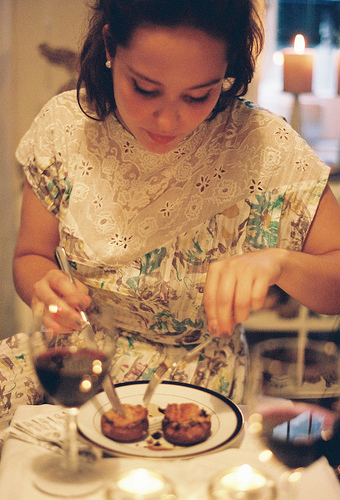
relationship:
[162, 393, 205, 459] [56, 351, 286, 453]
crab cake on plate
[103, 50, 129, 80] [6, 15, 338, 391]
earring on woman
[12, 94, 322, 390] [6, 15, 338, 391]
dress on woman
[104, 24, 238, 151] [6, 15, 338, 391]
face of woman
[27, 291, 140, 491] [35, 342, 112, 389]
glass has wine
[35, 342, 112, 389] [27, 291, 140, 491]
wine in glass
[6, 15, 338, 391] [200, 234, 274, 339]
woman has hand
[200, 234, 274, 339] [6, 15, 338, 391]
hand of woman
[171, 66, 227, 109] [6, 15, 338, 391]
eye of woman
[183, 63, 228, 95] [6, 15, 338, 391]
eyebrow of woman